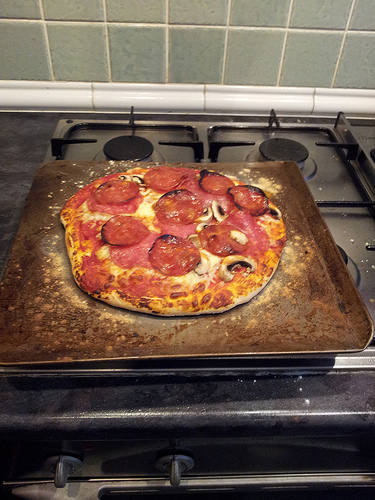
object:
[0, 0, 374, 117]
wall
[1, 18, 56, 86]
tile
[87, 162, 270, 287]
toppings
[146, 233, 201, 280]
pepperoni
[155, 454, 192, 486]
knob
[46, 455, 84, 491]
knob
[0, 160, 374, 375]
pan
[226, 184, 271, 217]
pepperoni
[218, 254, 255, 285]
mushroom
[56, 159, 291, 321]
pizza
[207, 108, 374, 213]
burner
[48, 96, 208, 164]
burner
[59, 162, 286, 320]
crust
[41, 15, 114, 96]
tiles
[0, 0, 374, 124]
backsplash